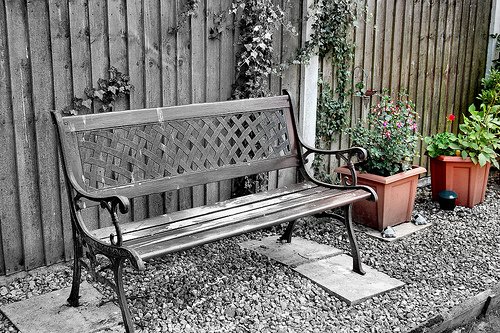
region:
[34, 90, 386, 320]
wooden garden bench next to fence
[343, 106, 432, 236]
plants growing in red planter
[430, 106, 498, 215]
plants growing in red planter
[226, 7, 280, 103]
vines growing along the fence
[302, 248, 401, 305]
paving stone supporting the bench foot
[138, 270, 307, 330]
gravel covering the ground under the bench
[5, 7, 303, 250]
wooden fence with vines growing upon it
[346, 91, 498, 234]
color section of a black and white photo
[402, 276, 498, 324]
wood landscape divider with rebar stake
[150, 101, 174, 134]
bird poop on the back of the bench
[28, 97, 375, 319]
bench on the ground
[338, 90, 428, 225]
pot with plant in it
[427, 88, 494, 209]
pot with plant in it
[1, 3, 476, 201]
fence behind the bench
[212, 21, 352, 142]
plant growing down fence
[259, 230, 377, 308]
blocks for bench feet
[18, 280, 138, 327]
block for bench feet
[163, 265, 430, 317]
rocks near bench area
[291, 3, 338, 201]
post in the fence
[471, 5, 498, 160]
post in the fence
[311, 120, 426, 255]
a square flower pot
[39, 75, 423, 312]
wooden park bench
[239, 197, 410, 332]
cement tile under bench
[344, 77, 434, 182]
green plant in pot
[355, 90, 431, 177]
pink flowers on plant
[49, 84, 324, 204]
lattice on back of bench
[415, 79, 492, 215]
red flower on plant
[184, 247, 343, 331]
gravel under the bench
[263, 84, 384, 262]
decorative arm rail on bench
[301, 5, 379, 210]
greenery going down fence